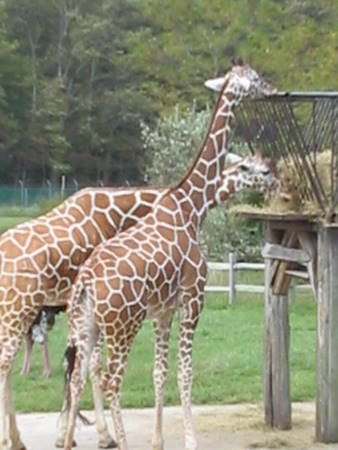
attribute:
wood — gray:
[316, 226, 336, 442]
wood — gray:
[261, 241, 310, 262]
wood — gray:
[270, 221, 318, 229]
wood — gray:
[283, 268, 308, 279]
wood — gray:
[264, 219, 290, 428]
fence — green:
[9, 185, 79, 213]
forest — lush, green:
[3, 1, 331, 103]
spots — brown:
[231, 82, 246, 93]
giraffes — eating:
[51, 50, 281, 448]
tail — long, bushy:
[60, 285, 80, 381]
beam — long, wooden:
[264, 222, 292, 432]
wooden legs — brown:
[258, 222, 337, 441]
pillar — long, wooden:
[260, 225, 294, 431]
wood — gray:
[260, 220, 337, 443]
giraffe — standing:
[62, 55, 277, 449]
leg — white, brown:
[174, 299, 205, 430]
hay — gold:
[227, 150, 335, 220]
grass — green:
[1, 293, 332, 410]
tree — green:
[139, 102, 271, 263]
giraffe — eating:
[0, 147, 283, 447]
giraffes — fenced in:
[57, 45, 290, 364]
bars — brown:
[229, 102, 328, 206]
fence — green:
[4, 184, 64, 208]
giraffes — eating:
[0, 55, 316, 383]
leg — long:
[181, 292, 206, 446]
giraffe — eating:
[64, 85, 245, 351]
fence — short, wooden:
[207, 256, 316, 301]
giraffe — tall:
[62, 147, 281, 448]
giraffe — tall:
[0, 60, 274, 448]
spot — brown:
[149, 270, 169, 290]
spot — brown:
[128, 253, 150, 278]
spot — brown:
[131, 278, 146, 294]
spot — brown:
[119, 278, 137, 302]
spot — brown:
[144, 303, 168, 315]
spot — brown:
[116, 260, 136, 277]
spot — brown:
[95, 251, 113, 262]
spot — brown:
[103, 241, 126, 257]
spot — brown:
[98, 301, 113, 313]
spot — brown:
[140, 241, 155, 253]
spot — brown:
[118, 236, 141, 251]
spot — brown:
[139, 225, 154, 236]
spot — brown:
[115, 233, 134, 239]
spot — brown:
[153, 249, 166, 263]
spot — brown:
[177, 262, 196, 292]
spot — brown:
[198, 262, 209, 276]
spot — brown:
[175, 228, 193, 254]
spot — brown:
[162, 242, 171, 257]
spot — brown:
[85, 220, 100, 248]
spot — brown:
[72, 224, 88, 252]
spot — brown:
[69, 206, 84, 222]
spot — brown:
[50, 215, 75, 227]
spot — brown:
[55, 201, 66, 212]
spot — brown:
[13, 229, 31, 247]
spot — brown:
[0, 260, 16, 277]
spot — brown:
[0, 271, 17, 292]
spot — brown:
[31, 248, 49, 271]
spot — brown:
[14, 221, 28, 230]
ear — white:
[240, 79, 258, 95]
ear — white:
[202, 77, 229, 94]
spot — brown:
[169, 240, 186, 268]